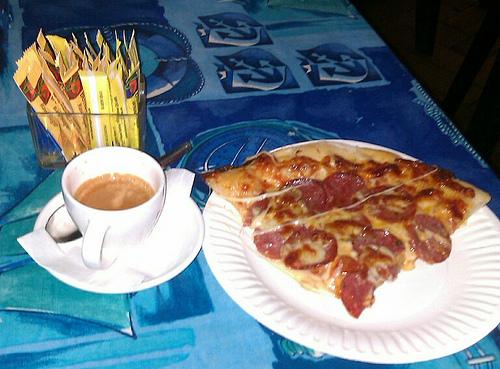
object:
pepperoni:
[327, 232, 369, 322]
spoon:
[44, 141, 192, 243]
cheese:
[410, 174, 459, 224]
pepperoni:
[306, 168, 378, 219]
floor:
[359, 0, 499, 169]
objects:
[61, 53, 116, 84]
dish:
[200, 138, 500, 352]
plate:
[328, 279, 495, 366]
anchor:
[229, 58, 287, 91]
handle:
[82, 219, 119, 270]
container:
[25, 78, 148, 170]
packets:
[121, 63, 141, 148]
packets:
[75, 68, 112, 150]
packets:
[13, 62, 68, 155]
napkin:
[163, 168, 194, 241]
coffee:
[32, 146, 202, 295]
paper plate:
[203, 247, 388, 363]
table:
[0, 0, 500, 369]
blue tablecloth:
[0, 1, 500, 369]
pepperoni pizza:
[201, 147, 490, 319]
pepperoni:
[283, 230, 338, 268]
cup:
[59, 145, 164, 270]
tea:
[71, 172, 156, 210]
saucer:
[30, 185, 206, 294]